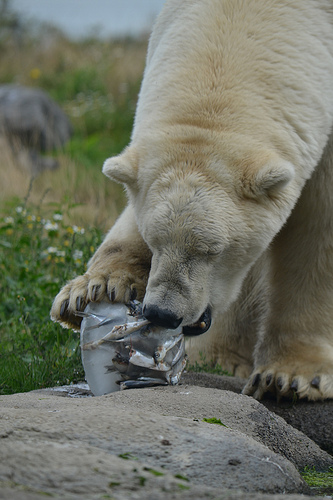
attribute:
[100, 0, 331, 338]
bear — polar 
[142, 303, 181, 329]
nose — black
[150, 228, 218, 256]
eyes — bear's , closed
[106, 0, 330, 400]
bear — white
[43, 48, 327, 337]
bear — polar 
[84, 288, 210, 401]
fish —  small 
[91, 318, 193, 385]
fish — dead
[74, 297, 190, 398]
block — frozen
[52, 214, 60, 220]
white flower — Small white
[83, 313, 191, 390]
fish — grey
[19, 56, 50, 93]
flower — yellow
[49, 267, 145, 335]
claw — His 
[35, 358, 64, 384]
grass`s part — part 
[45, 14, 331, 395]
bear — polar , white., white, furry, biting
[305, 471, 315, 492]
plant — part  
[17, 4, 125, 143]
background — blurry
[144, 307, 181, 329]
nose — black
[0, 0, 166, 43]
sky — clear blue 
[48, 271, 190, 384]
claw — His 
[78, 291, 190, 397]
base — part  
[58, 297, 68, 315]
nail — dark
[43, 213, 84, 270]
flowers — Small yellow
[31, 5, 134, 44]
sky — pale blue 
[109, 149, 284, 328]
bear — polar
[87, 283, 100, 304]
claw — black 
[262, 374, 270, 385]
claw — black 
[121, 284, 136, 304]
claw — black 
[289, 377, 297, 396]
claw — black 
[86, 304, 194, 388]
fish — white 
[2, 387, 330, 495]
rock — light grey.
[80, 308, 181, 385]
ice — block 